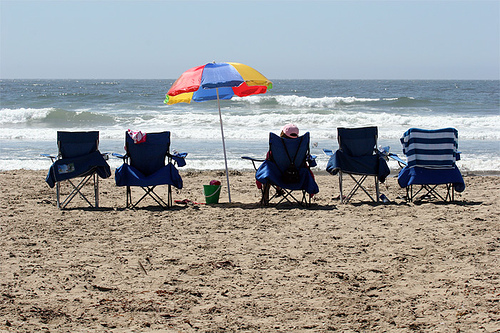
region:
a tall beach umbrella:
[144, 45, 315, 266]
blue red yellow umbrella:
[89, 22, 294, 256]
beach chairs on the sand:
[36, 50, 498, 294]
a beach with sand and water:
[52, 57, 392, 306]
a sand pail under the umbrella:
[187, 156, 247, 232]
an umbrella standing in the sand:
[167, 35, 289, 235]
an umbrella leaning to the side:
[159, 35, 285, 230]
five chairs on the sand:
[3, 60, 497, 285]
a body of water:
[305, 87, 415, 132]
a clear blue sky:
[312, 13, 435, 55]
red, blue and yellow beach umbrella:
[163, 59, 280, 114]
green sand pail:
[192, 175, 227, 211]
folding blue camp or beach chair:
[42, 119, 118, 216]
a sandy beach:
[9, 222, 493, 314]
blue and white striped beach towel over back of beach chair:
[395, 126, 474, 172]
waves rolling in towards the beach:
[260, 89, 417, 125]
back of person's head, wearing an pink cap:
[269, 119, 321, 146]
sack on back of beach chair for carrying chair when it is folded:
[41, 151, 116, 185]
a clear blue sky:
[14, 9, 494, 60]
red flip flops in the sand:
[170, 191, 207, 208]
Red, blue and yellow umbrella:
[161, 51, 272, 209]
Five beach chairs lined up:
[33, 98, 479, 245]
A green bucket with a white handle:
[196, 167, 228, 212]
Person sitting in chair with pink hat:
[254, 121, 331, 205]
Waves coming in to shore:
[2, 73, 462, 162]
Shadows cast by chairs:
[55, 193, 492, 221]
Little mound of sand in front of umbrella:
[198, 158, 243, 185]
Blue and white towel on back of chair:
[398, 109, 480, 217]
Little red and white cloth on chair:
[121, 123, 152, 150]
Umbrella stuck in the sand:
[161, 53, 271, 240]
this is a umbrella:
[179, 68, 267, 88]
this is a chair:
[406, 110, 463, 184]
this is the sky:
[299, 20, 490, 55]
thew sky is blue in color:
[281, 27, 350, 60]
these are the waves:
[293, 94, 346, 119]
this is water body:
[396, 74, 483, 91]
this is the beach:
[178, 221, 410, 286]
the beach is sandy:
[218, 222, 384, 329]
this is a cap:
[290, 122, 307, 141]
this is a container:
[206, 178, 221, 198]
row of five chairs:
[12, 37, 495, 245]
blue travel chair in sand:
[34, 112, 114, 205]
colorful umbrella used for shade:
[141, 31, 269, 243]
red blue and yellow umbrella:
[149, 44, 291, 119]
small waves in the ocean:
[26, 40, 480, 205]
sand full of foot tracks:
[18, 166, 475, 319]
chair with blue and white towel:
[390, 114, 476, 227]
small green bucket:
[195, 169, 233, 212]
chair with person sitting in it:
[237, 118, 346, 271]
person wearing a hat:
[255, 103, 309, 173]